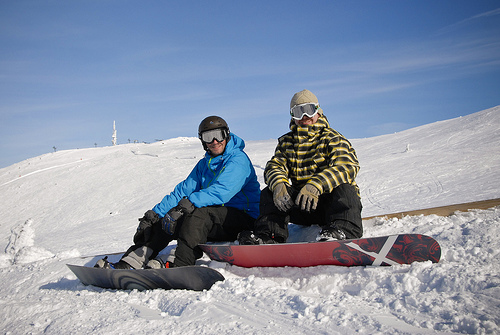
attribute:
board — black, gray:
[103, 264, 185, 290]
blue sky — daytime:
[2, 2, 498, 98]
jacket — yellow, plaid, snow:
[259, 114, 366, 196]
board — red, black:
[215, 210, 490, 261]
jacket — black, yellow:
[261, 106, 361, 203]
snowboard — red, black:
[192, 227, 444, 266]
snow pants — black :
[135, 204, 241, 266]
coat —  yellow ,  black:
[262, 118, 359, 193]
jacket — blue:
[153, 139, 268, 223]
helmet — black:
[193, 116, 235, 150]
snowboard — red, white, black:
[205, 230, 492, 292]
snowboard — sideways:
[214, 233, 441, 268]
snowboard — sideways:
[68, 248, 228, 288]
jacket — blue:
[154, 133, 271, 222]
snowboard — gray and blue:
[66, 262, 225, 292]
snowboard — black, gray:
[65, 259, 223, 297]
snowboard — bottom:
[208, 247, 435, 263]